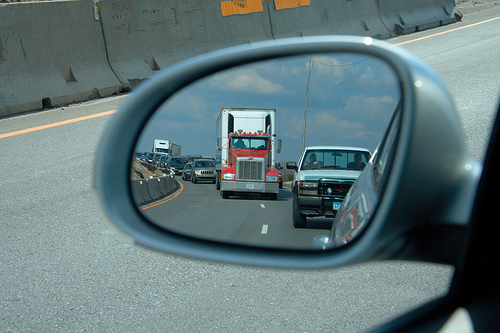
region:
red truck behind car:
[218, 130, 283, 195]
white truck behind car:
[286, 143, 374, 224]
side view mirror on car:
[130, 46, 404, 253]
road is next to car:
[0, 10, 498, 330]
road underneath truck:
[138, 175, 338, 252]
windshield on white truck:
[300, 150, 372, 168]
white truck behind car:
[151, 138, 179, 155]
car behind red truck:
[187, 158, 214, 182]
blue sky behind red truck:
[137, 52, 402, 166]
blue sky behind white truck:
[134, 50, 398, 161]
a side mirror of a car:
[76, 51, 445, 281]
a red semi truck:
[208, 103, 289, 203]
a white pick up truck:
[284, 138, 364, 227]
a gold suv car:
[192, 158, 219, 185]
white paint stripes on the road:
[256, 200, 276, 239]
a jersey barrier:
[5, 4, 173, 117]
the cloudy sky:
[273, 70, 390, 120]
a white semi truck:
[153, 134, 188, 156]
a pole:
[302, 61, 314, 151]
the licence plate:
[243, 180, 263, 189]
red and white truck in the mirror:
[210, 99, 287, 201]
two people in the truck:
[306, 150, 364, 170]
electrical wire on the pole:
[283, 54, 368, 130]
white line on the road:
[252, 221, 274, 240]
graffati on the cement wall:
[105, 5, 187, 32]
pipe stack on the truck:
[263, 122, 273, 135]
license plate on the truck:
[330, 199, 341, 210]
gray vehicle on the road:
[195, 159, 217, 183]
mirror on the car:
[95, 33, 446, 278]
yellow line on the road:
[41, 109, 71, 139]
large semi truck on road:
[203, 108, 283, 194]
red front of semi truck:
[215, 131, 280, 200]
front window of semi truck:
[232, 135, 277, 152]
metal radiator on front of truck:
[232, 156, 265, 183]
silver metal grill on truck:
[237, 160, 266, 179]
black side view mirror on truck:
[289, 160, 297, 170]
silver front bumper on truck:
[212, 179, 289, 193]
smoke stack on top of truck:
[263, 120, 270, 132]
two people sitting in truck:
[303, 153, 365, 168]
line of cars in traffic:
[148, 133, 209, 190]